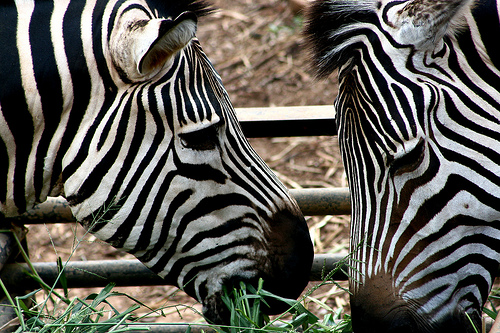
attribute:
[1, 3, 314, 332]
zebra — black, white, grazing, close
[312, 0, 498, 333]
zebra — grazing, close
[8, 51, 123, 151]
stripes — black, white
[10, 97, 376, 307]
fence — grey, metal, discolored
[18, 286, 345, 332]
grass — green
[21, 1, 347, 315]
ground — brown, dry, dirt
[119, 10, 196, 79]
ear — black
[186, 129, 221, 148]
eye — black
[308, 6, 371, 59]
mane — bushy, black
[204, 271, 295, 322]
mouth — black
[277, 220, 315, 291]
nose — black